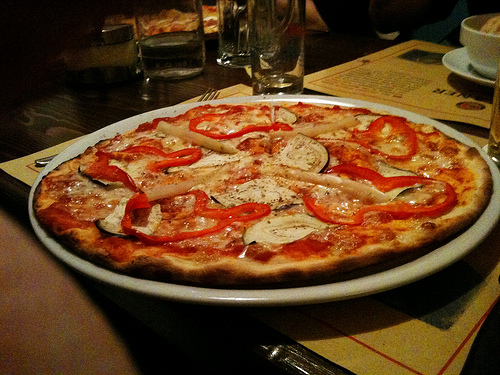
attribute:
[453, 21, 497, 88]
bowl — small, white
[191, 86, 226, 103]
fork — silver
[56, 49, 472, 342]
plate — round, white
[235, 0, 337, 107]
glass — clear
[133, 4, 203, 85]
glass — Thicker , clear 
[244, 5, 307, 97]
glass — Thick, clear 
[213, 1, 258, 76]
glass — Thick, clear 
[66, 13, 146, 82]
glass — Thick, clear 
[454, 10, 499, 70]
bowl — white 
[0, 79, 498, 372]
place mat — paper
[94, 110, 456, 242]
peppers — Red 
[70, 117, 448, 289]
pizza — whole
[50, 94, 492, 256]
pizza — vegetable 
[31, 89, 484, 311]
tray — gray